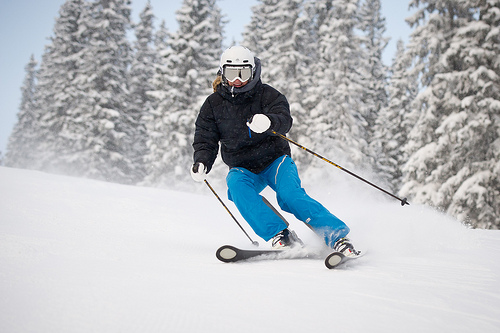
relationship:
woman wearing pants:
[206, 47, 273, 115] [229, 156, 345, 239]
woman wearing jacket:
[206, 47, 273, 115] [170, 90, 296, 164]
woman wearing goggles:
[206, 47, 273, 115] [220, 67, 266, 83]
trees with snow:
[45, 22, 460, 205] [157, 39, 186, 103]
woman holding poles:
[206, 47, 273, 115] [197, 139, 385, 246]